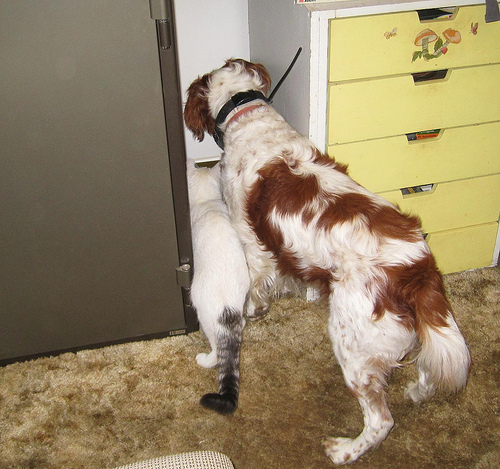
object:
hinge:
[152, 4, 174, 47]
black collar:
[212, 90, 273, 146]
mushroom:
[406, 26, 465, 66]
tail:
[407, 275, 474, 402]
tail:
[195, 308, 242, 414]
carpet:
[0, 270, 500, 469]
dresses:
[320, 186, 406, 239]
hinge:
[175, 260, 191, 291]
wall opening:
[171, 0, 316, 304]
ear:
[183, 74, 210, 140]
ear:
[239, 54, 272, 91]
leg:
[196, 316, 221, 355]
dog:
[183, 58, 469, 468]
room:
[0, 2, 497, 469]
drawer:
[325, 60, 498, 147]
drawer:
[322, 120, 499, 193]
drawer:
[363, 172, 500, 235]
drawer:
[423, 223, 499, 275]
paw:
[195, 350, 217, 368]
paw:
[320, 432, 357, 466]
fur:
[287, 163, 320, 228]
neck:
[216, 95, 277, 135]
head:
[187, 158, 220, 202]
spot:
[288, 187, 314, 209]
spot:
[367, 213, 424, 239]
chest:
[245, 2, 500, 273]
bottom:
[150, 0, 198, 340]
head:
[181, 54, 270, 144]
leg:
[341, 348, 394, 441]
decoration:
[408, 26, 461, 61]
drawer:
[329, 0, 500, 83]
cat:
[186, 160, 254, 414]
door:
[1, 0, 198, 370]